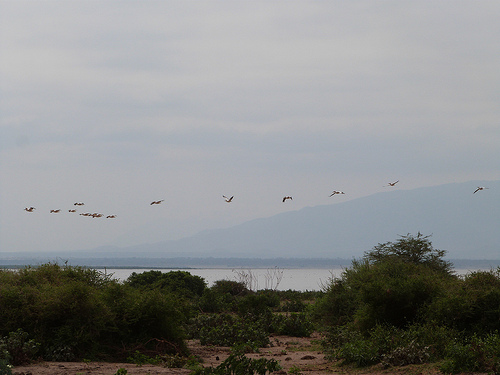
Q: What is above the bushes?
A: Birds.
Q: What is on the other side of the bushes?
A: Water.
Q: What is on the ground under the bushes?
A: Dirt.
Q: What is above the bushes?
A: Birds.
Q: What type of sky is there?
A: Hazy.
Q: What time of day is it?
A: Evening.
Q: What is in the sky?
A: Clouds.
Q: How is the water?
A: Calm.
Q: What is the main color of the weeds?
A: Green.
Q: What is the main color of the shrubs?
A: Green.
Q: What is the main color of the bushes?
A: Green.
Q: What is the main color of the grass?
A: Green.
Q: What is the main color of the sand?
A: Brown.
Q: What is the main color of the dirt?
A: Brown.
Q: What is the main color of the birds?
A: White.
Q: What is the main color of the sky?
A: Blue.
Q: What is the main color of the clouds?
A: White.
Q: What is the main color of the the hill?
A: Blue.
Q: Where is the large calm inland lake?
A: Beyond the shoreline.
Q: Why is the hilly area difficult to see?
A: Hazy smog sky.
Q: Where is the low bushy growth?
A: Far left picture.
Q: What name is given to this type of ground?
A: Hardpan earth.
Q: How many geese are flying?
A: 13.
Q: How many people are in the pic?
A: None.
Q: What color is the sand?
A: Tan.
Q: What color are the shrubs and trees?
A: Green.